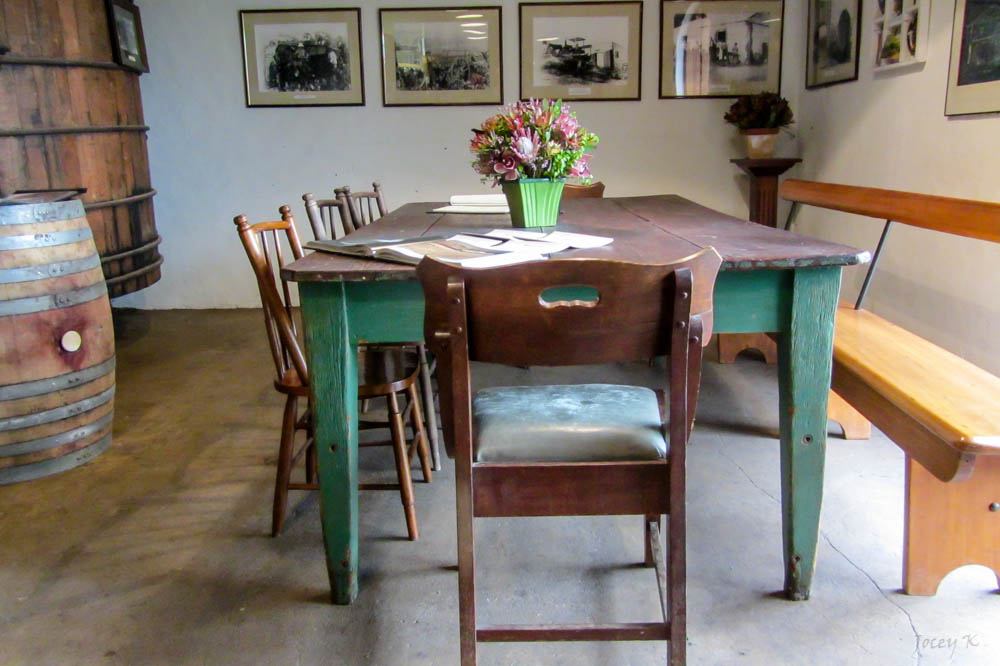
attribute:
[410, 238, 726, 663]
chair — wooden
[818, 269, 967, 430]
bench — wooden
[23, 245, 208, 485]
barrel — large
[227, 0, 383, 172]
picture — hanging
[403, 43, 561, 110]
picture — hanging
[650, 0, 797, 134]
picture — hanging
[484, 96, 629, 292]
flower — green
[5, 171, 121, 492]
barrel — wood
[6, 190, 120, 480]
barrel — striped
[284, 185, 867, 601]
table — green